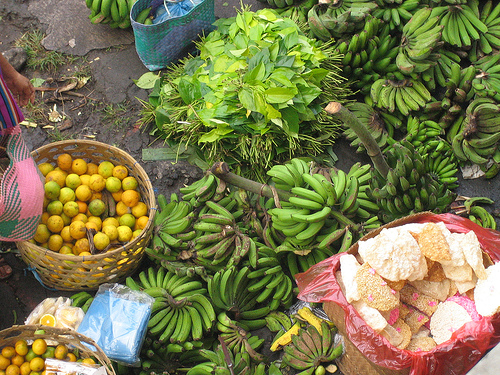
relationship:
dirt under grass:
[46, 96, 158, 148] [0, 0, 273, 167]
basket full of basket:
[12, 137, 158, 290] [1, 318, 112, 372]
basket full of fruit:
[12, 137, 158, 290] [2, 24, 496, 374]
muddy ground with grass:
[44, 58, 142, 131] [87, 85, 150, 132]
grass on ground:
[96, 95, 143, 130] [3, 2, 225, 186]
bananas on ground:
[268, 157, 372, 254] [3, 1, 481, 371]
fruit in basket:
[87, 170, 100, 187] [33, 133, 161, 279]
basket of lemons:
[18, 132, 151, 294] [29, 157, 134, 244]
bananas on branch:
[265, 163, 372, 257] [211, 157, 285, 198]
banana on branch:
[438, 156, 451, 170] [209, 157, 294, 199]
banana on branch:
[397, 175, 409, 191] [326, 100, 393, 175]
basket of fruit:
[12, 137, 158, 290] [87, 172, 105, 190]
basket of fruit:
[12, 137, 158, 290] [75, 185, 90, 200]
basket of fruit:
[12, 137, 158, 290] [63, 200, 80, 217]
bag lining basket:
[298, 211, 482, 371] [18, 232, 111, 277]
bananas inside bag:
[130, 5, 154, 27] [128, 0, 219, 72]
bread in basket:
[355, 223, 427, 283] [290, 210, 495, 373]